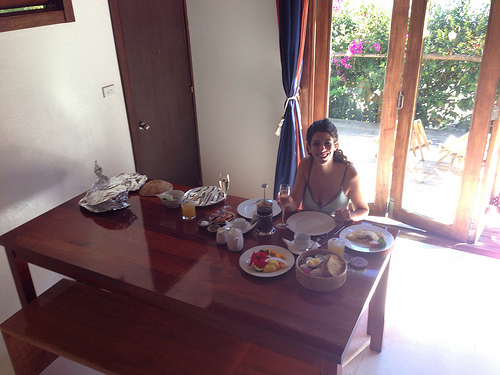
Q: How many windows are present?
A: Two.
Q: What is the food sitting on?
A: A table.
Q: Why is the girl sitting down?
A: So she can eat.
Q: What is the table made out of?
A: Wood.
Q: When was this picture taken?
A: During the day.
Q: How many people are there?
A: One.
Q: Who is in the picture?
A: A woman.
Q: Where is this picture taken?
A: A dining area.